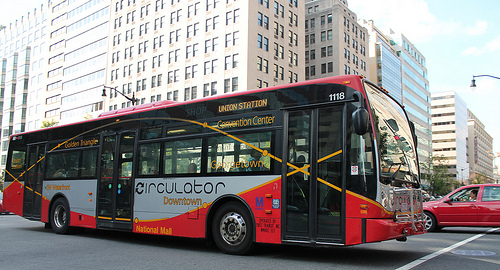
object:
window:
[259, 33, 274, 48]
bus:
[0, 74, 427, 256]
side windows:
[8, 127, 104, 181]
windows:
[203, 126, 279, 177]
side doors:
[283, 105, 346, 245]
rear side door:
[25, 138, 45, 217]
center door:
[98, 128, 136, 226]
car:
[423, 182, 499, 232]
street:
[0, 250, 497, 270]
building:
[428, 88, 493, 184]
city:
[1, 1, 498, 270]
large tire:
[210, 198, 254, 254]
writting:
[135, 180, 225, 207]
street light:
[469, 75, 499, 89]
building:
[109, 1, 307, 80]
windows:
[257, 12, 272, 32]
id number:
[329, 92, 346, 101]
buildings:
[305, 1, 369, 77]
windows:
[319, 12, 333, 27]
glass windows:
[375, 45, 427, 88]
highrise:
[404, 33, 435, 200]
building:
[248, 1, 371, 77]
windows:
[431, 92, 457, 163]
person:
[468, 187, 478, 203]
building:
[2, 1, 103, 118]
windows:
[24, 45, 32, 64]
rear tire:
[49, 196, 71, 232]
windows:
[433, 120, 456, 127]